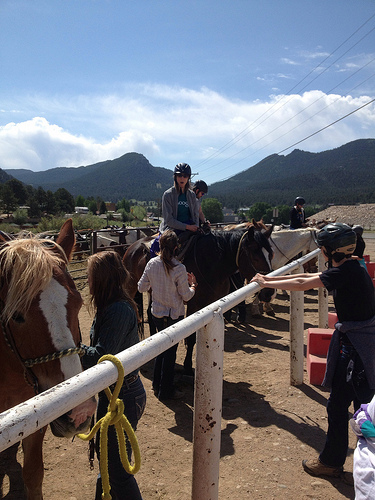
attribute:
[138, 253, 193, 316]
shirt — white, long sleeve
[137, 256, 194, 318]
shirt — white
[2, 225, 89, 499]
horse — white , brown 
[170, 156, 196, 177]
helmet — black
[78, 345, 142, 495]
rope — yellow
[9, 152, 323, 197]
mountain chain — small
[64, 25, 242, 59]
sky — blue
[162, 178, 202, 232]
cardigan — gray 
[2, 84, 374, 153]
clouds — white, fluffy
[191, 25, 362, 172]
powerline — overhead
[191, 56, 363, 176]
powerline — overhead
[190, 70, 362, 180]
powerline — overhead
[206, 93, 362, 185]
powerline — overhead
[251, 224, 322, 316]
horse — white